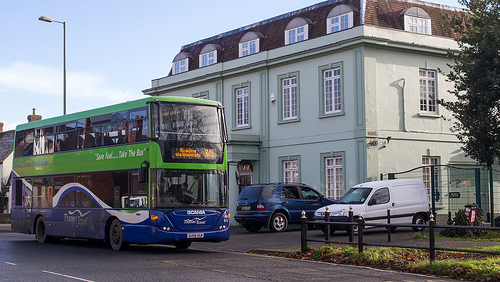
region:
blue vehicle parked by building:
[231, 175, 326, 230]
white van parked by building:
[312, 181, 424, 229]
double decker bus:
[12, 90, 239, 251]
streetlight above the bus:
[28, 13, 88, 110]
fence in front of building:
[307, 215, 432, 260]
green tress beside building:
[443, 13, 498, 174]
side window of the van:
[369, 184, 391, 209]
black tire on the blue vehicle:
[269, 213, 287, 234]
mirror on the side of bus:
[136, 157, 150, 184]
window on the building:
[320, 58, 347, 125]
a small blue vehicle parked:
[228, 175, 333, 235]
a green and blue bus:
[5, 85, 230, 240]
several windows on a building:
[260, 51, 341, 206]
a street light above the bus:
[32, 11, 67, 111]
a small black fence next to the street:
[295, 200, 496, 257]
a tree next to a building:
[426, 0, 496, 170]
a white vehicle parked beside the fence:
[305, 167, 437, 253]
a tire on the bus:
[103, 213, 124, 253]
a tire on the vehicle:
[409, 212, 426, 233]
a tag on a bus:
[184, 229, 206, 240]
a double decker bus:
[3, 98, 255, 255]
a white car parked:
[319, 173, 431, 236]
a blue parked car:
[228, 173, 338, 245]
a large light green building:
[143, 1, 497, 270]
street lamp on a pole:
[26, 9, 96, 123]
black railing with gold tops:
[301, 205, 483, 272]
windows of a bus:
[12, 117, 120, 158]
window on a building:
[272, 69, 309, 123]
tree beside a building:
[452, 6, 499, 160]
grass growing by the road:
[306, 239, 473, 276]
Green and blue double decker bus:
[8, 93, 231, 245]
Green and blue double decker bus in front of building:
[7, 97, 229, 253]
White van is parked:
[313, 180, 428, 232]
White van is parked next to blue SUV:
[315, 179, 428, 243]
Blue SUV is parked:
[235, 176, 335, 233]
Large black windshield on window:
[200, 194, 226, 218]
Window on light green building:
[280, 72, 303, 124]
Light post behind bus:
[37, 8, 67, 116]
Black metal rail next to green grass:
[295, 203, 499, 278]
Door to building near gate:
[445, 160, 491, 218]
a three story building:
[144, 1, 499, 228]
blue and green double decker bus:
[11, 95, 226, 252]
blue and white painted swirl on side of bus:
[41, 177, 153, 229]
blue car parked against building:
[232, 177, 337, 237]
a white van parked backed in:
[315, 171, 436, 234]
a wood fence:
[297, 198, 495, 268]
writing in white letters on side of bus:
[91, 142, 151, 166]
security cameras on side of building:
[367, 128, 394, 157]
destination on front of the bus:
[159, 137, 231, 168]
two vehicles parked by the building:
[227, 143, 436, 254]